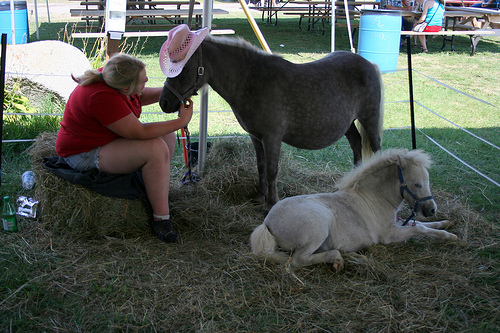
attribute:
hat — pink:
[156, 13, 212, 70]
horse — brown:
[199, 39, 389, 174]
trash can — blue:
[344, 6, 406, 81]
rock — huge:
[7, 39, 77, 118]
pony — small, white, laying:
[247, 142, 460, 287]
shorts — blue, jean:
[58, 143, 104, 173]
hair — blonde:
[67, 55, 147, 96]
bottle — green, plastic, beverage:
[2, 193, 22, 235]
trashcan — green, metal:
[356, 7, 403, 76]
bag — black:
[357, 6, 404, 17]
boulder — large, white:
[3, 37, 92, 125]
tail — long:
[357, 62, 386, 164]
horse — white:
[245, 147, 464, 290]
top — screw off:
[1, 190, 11, 203]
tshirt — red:
[53, 80, 144, 159]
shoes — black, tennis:
[146, 214, 181, 244]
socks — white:
[150, 210, 174, 227]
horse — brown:
[155, 28, 387, 220]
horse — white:
[247, 144, 461, 274]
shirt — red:
[51, 74, 144, 157]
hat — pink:
[155, 21, 212, 79]